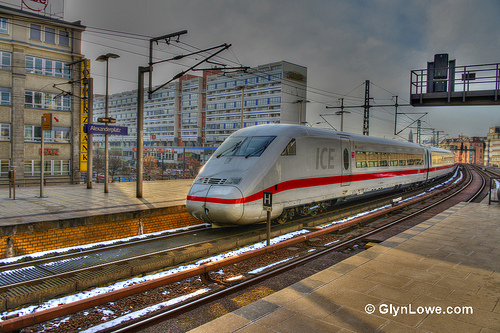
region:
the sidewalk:
[408, 255, 475, 305]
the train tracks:
[82, 245, 137, 268]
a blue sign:
[86, 120, 129, 138]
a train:
[217, 143, 414, 187]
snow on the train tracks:
[203, 248, 240, 263]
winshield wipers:
[245, 143, 262, 160]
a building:
[203, 80, 235, 135]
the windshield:
[228, 135, 263, 154]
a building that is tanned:
[478, 135, 498, 170]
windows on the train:
[358, 149, 411, 167]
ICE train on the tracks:
[187, 123, 454, 225]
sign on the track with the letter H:
[262, 192, 272, 241]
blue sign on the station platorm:
[86, 122, 126, 134]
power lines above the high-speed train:
[16, 28, 445, 139]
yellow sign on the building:
[79, 60, 92, 168]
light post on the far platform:
[100, 51, 118, 193]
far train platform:
[0, 178, 203, 231]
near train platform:
[187, 200, 493, 330]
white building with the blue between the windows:
[101, 62, 306, 144]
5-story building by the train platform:
[3, 17, 91, 182]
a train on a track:
[10, 16, 492, 311]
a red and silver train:
[192, 89, 479, 226]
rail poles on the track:
[95, 33, 230, 195]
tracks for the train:
[18, 213, 300, 309]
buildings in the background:
[438, 123, 498, 180]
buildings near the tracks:
[93, 56, 311, 181]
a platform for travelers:
[206, 210, 497, 329]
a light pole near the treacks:
[95, 53, 133, 196]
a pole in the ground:
[31, 105, 56, 202]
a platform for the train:
[402, 48, 499, 110]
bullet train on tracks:
[188, 124, 353, 207]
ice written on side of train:
[292, 130, 357, 192]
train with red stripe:
[204, 125, 441, 211]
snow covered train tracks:
[5, 221, 345, 293]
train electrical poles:
[98, 33, 418, 127]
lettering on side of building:
[65, 53, 105, 189]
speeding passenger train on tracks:
[201, 118, 456, 200]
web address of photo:
[359, 289, 495, 331]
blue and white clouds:
[216, 6, 486, 53]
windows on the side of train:
[348, 139, 436, 184]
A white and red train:
[184, 124, 458, 226]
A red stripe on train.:
[187, 162, 459, 210]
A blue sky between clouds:
[395, 19, 427, 46]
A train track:
[0, 162, 499, 332]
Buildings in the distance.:
[420, 125, 498, 170]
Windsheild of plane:
[210, 128, 277, 157]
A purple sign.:
[81, 125, 130, 135]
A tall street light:
[94, 50, 121, 192]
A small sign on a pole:
[260, 189, 273, 246]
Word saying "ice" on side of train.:
[314, 146, 335, 168]